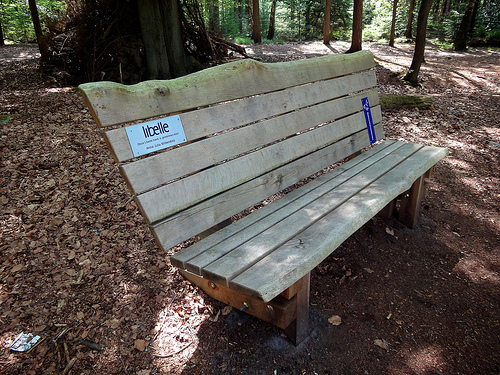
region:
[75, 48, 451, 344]
a wooden park bench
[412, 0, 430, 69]
a dark brown tree trunk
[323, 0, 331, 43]
a dark brown tree trunk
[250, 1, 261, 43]
a dark brown tree trunk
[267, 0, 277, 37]
a dark brown tree trunk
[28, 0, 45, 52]
a dark brown tree trunk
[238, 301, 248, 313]
a metal screw and bolt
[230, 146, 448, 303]
a brown wood slat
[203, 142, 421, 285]
a weathered brown wood slat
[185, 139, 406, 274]
a weathered brown wood slat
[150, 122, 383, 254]
a weathered brown wood slat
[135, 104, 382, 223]
a weathered brown wood slat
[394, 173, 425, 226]
a brown wood leg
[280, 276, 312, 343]
a brown wood leg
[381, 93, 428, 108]
a patch of green grass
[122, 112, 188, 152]
a sign on the bench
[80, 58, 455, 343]
a wooden bench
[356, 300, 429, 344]
dirt on the ground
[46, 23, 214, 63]
a large tree trunk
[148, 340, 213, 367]
sticks on the ground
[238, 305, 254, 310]
a bolt on the bench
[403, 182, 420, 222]
the stands of the bench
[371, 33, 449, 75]
shadow on the ground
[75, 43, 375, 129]
wood slat on the park bench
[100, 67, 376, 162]
wood slat on the park bench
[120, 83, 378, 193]
wood slat on the park bench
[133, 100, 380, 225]
wood slat on the park bench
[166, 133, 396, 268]
wood slat on the park bench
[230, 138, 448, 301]
wood slat on the park bench